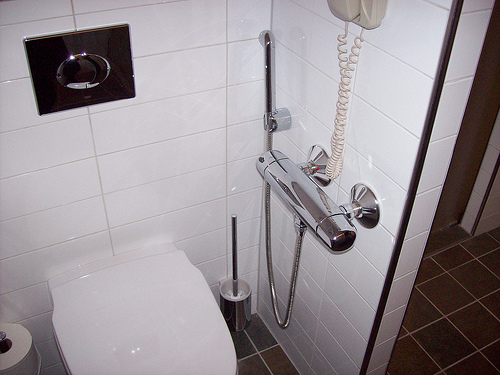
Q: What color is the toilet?
A: White.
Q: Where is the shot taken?
A: Bathroom.